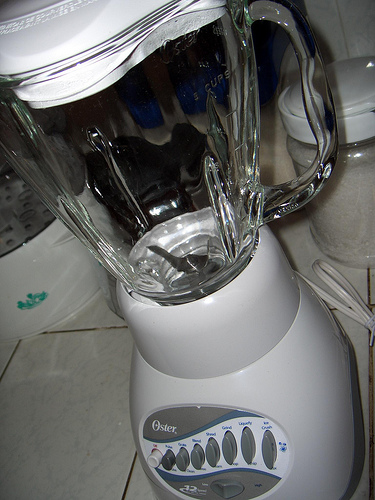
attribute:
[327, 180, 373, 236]
storage jar — white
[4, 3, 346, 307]
glass — cup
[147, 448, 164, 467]
button — white, small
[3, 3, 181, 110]
lid — white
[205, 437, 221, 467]
button — grey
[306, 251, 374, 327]
cord — white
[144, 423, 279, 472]
buttons — small, gray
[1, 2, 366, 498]
blender — Oster, white, twelve speed , electric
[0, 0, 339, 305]
jar — glass, clear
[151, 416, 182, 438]
symbol — white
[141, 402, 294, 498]
button — grey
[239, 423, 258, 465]
button — grey